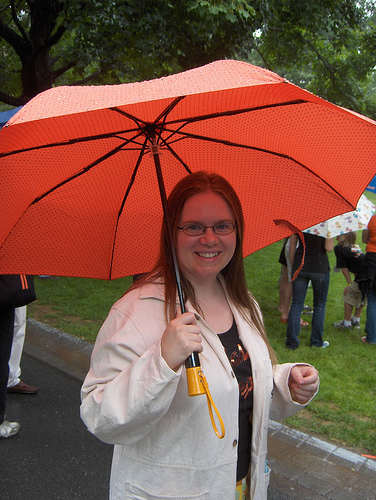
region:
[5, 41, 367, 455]
woman holding a red umbrella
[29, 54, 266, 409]
red umbrella with yellow handle and strap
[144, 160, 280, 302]
woman wearing black rimmed glasses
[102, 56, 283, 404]
smiling woman carrying a red umbrella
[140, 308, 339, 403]
two hands of a woman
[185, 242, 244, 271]
smile on the face of a woman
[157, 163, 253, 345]
woman with long brown hair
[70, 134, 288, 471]
woman wearing a white jacket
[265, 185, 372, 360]
people standing under an umbrella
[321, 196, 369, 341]
child standing under an umbrella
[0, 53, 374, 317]
orange umbrella with black dots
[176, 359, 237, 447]
yellow handle and strap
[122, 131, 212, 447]
lady holding black handle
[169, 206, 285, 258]
lady wearing black rimmed glasses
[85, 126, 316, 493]
lady wearing white coat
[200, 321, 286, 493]
lady wearing black top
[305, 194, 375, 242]
white umbrella with colorful bows on it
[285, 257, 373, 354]
lady wearing jeans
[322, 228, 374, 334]
little boy under umbrella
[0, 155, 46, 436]
guy wearing white pants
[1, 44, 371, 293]
a red umbrella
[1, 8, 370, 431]
a woman holding a red umbrella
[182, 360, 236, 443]
yellow tip of an umbrella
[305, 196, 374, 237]
a white umbrella with colorful patterns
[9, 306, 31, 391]
a person wearing white pants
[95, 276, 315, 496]
woman wearing a white jacket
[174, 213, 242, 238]
woman wearing glasses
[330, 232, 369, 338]
kid holding his knees with the palm of his hands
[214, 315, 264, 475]
woman wearing black T-shirt with orange lettering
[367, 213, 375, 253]
person wearing an orange shirt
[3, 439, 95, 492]
a paved road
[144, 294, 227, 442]
hand holding umbrella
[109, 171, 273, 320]
woman with an opened umbrella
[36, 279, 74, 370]
green grass and the curb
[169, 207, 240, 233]
glasses on a woman's face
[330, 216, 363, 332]
boy leaning under an umbrella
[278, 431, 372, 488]
brick work at the edge of the road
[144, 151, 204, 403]
log black handle with yellow tip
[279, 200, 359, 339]
three people gathered under an umbrella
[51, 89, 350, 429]
smiling woman in the rain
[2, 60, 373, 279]
an open red umbrella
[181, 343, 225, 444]
a black and yellow umbrella handle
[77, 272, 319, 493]
a women's white coat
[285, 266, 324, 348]
a pair of women's blue jeans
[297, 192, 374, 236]
a colorful umbrella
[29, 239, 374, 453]
a patch of green grass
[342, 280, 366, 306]
a pair of child's khaki short pants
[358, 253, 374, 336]
a pair of blue jeans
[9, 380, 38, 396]
a brown shoe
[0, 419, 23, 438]
a white and grey tennis shoe